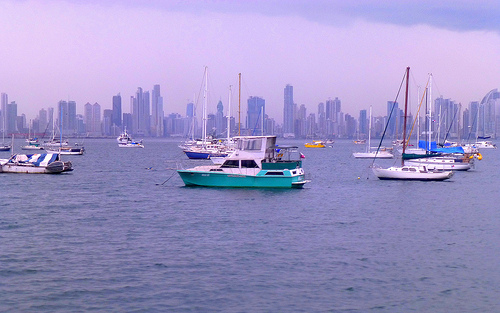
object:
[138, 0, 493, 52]
cloud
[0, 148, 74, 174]
boat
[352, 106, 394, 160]
boat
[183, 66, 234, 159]
boat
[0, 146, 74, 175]
floater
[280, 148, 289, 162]
door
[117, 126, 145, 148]
boat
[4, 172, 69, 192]
water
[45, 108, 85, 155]
boat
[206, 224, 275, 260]
water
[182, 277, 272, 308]
water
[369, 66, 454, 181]
boat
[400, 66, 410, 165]
pole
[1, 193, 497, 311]
sea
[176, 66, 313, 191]
boat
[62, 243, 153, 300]
water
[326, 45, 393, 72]
sky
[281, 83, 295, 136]
building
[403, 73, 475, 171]
boat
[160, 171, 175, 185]
rope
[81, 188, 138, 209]
water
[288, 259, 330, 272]
water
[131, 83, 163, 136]
building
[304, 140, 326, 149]
boat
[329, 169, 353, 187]
water